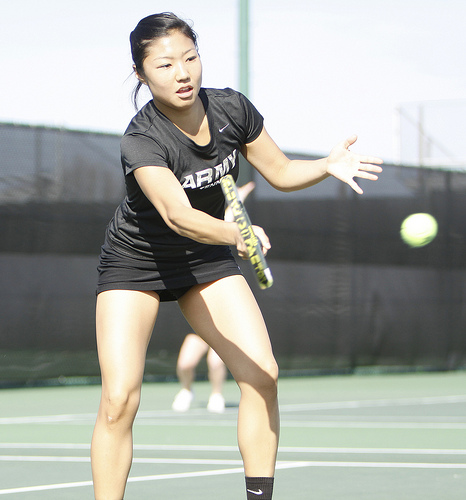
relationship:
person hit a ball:
[93, 13, 384, 499] [399, 211, 439, 251]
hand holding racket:
[238, 227, 270, 264] [222, 166, 274, 293]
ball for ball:
[403, 212, 438, 248] [399, 211, 439, 251]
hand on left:
[325, 137, 382, 201] [258, 11, 460, 497]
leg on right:
[95, 292, 161, 499] [1, 7, 237, 499]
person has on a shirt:
[93, 13, 384, 499] [106, 86, 265, 259]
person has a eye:
[93, 13, 384, 499] [164, 61, 172, 71]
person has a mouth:
[93, 13, 384, 499] [173, 85, 195, 96]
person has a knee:
[93, 13, 384, 499] [259, 357, 282, 385]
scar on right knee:
[129, 382, 140, 403] [259, 357, 282, 385]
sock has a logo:
[244, 476, 274, 499] [248, 487, 263, 497]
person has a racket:
[93, 13, 384, 499] [222, 166, 274, 293]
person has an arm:
[93, 13, 384, 499] [136, 168, 270, 262]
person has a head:
[93, 13, 384, 499] [132, 16, 201, 110]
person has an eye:
[93, 13, 384, 499] [164, 61, 172, 71]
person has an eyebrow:
[93, 13, 384, 499] [182, 52, 194, 56]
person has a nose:
[93, 13, 384, 499] [180, 68, 191, 82]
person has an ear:
[93, 13, 384, 499] [133, 68, 145, 86]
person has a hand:
[93, 13, 384, 499] [238, 227, 270, 264]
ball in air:
[403, 212, 438, 248] [1, 7, 465, 499]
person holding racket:
[93, 13, 384, 499] [222, 166, 274, 293]